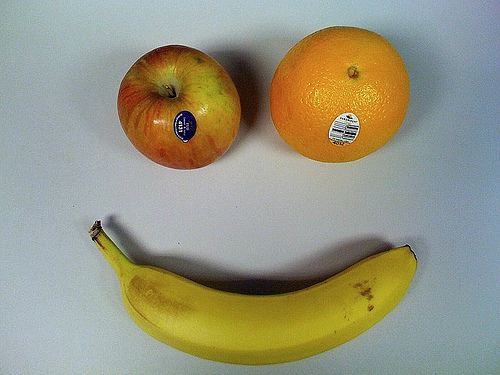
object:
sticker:
[328, 109, 360, 150]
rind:
[319, 88, 364, 149]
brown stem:
[164, 84, 175, 95]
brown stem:
[87, 219, 107, 248]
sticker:
[329, 111, 357, 146]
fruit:
[271, 26, 410, 163]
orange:
[269, 25, 408, 164]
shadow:
[105, 214, 430, 314]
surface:
[224, 184, 316, 256]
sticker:
[170, 109, 198, 142]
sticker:
[160, 112, 211, 145]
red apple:
[114, 40, 245, 172]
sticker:
[171, 105, 198, 143]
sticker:
[325, 112, 362, 154]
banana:
[89, 218, 417, 365]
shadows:
[194, 27, 257, 70]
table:
[98, 166, 460, 227]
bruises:
[367, 294, 374, 300]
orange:
[268, 14, 428, 174]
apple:
[117, 45, 241, 170]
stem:
[87, 217, 132, 277]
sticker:
[322, 108, 357, 148]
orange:
[264, 24, 413, 166]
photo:
[3, 52, 493, 303]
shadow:
[132, 248, 389, 297]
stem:
[84, 210, 106, 240]